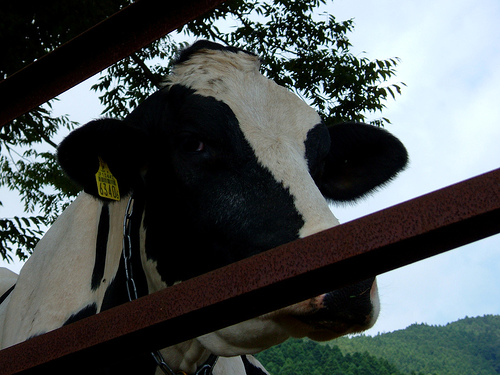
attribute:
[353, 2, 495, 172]
sky — blue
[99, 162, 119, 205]
tag — yellow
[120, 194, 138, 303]
chain — silver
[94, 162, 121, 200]
tag —  yellow,  6340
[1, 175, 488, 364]
fence — metal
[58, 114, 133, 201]
ear — cow's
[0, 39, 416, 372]
cow — black, white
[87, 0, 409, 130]
leaves — green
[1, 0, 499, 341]
sky — blue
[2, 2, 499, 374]
fence — maroon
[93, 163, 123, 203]
tag — yellow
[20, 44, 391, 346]
cow — contented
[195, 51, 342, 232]
stripe — white